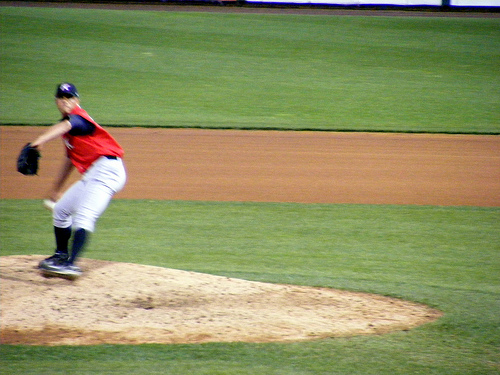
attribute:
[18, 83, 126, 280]
man — throwing, preparing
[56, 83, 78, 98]
hat — blue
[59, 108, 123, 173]
shirt — red, orange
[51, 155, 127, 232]
pants — white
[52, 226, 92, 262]
socks — black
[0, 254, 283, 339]
mound — brown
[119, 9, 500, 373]
field — green, untouched, brown, clipped, orange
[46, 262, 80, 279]
foot — raised, tan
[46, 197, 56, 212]
ball — held